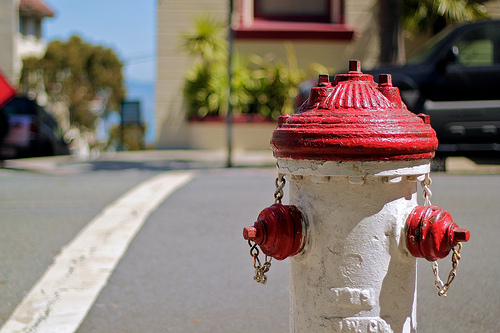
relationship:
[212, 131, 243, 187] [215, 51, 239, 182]
tall grey metal street sign post